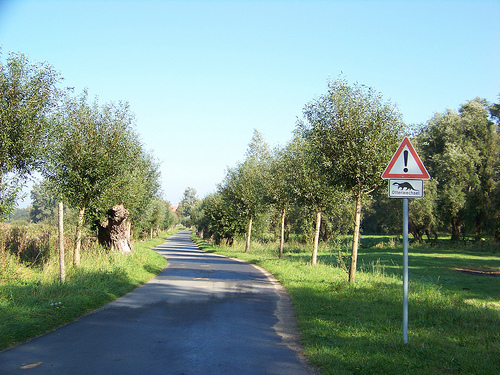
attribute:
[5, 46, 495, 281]
trees — old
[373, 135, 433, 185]
street sign — black, white, red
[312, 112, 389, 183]
leaves — light, green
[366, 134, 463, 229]
sign — triangle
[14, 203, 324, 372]
road — long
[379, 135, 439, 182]
sign — black, white, red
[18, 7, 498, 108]
sky — blue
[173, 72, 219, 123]
clouds — white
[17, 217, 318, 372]
path — long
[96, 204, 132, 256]
stump — large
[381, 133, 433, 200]
sign — designating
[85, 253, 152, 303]
tall grass — green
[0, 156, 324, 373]
road — paved, small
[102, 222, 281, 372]
path — empty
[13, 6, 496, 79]
sky — blue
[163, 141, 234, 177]
clouds — white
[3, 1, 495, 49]
sky — blue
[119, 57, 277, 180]
clouds — white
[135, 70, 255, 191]
clouds — white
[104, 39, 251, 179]
clouds — white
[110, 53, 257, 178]
clouds — white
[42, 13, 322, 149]
sun — shining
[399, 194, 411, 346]
pole — metal, gray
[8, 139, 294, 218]
cloud — white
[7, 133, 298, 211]
cloud — white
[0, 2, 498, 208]
sky — blue